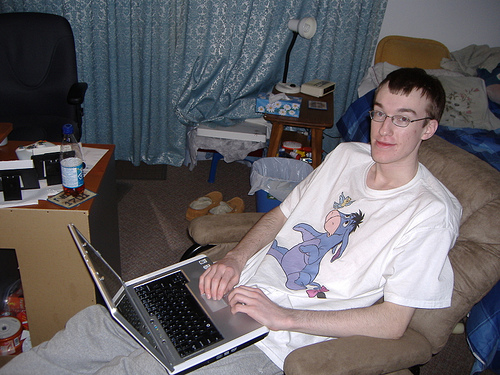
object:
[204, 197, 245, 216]
shoes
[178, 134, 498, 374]
chair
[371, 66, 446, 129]
hair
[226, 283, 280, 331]
left hand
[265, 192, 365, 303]
cartoon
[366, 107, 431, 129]
spectacles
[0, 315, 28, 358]
paint can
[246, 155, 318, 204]
trash bag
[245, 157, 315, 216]
garbage can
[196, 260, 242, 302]
hand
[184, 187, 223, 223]
shoe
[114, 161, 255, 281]
floor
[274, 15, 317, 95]
lamp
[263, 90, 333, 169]
desk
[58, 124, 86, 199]
bottle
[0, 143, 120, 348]
table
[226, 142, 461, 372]
t shirt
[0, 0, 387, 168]
curtain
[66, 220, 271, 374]
laptop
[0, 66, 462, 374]
man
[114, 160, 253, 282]
carpet